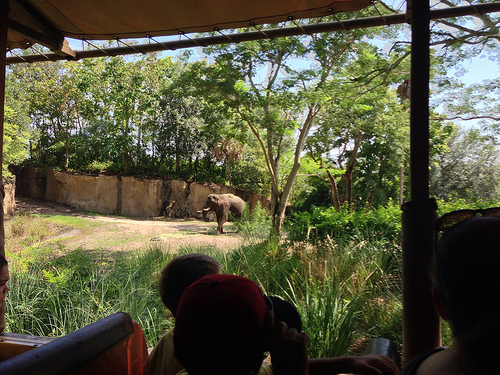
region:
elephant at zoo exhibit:
[179, 184, 265, 244]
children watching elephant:
[140, 227, 305, 369]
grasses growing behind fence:
[275, 235, 365, 335]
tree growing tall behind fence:
[229, 70, 304, 259]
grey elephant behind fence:
[195, 173, 262, 237]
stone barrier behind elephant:
[38, 140, 163, 226]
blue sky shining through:
[157, 44, 333, 137]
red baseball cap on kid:
[167, 264, 294, 359]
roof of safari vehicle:
[120, 9, 345, 132]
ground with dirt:
[92, 213, 164, 250]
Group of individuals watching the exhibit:
[149, 211, 496, 368]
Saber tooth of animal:
[198, 206, 211, 214]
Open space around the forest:
[4, 218, 215, 247]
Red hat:
[179, 281, 299, 349]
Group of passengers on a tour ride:
[149, 209, 495, 371]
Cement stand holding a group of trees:
[10, 166, 208, 217]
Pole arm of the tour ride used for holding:
[402, 23, 436, 358]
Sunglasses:
[434, 203, 495, 230]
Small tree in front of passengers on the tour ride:
[174, 35, 408, 238]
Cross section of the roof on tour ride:
[0, 3, 402, 75]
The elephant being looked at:
[193, 187, 253, 234]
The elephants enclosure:
[1, 24, 485, 363]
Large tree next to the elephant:
[189, 0, 372, 248]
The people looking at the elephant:
[129, 207, 496, 372]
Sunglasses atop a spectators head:
[432, 202, 498, 228]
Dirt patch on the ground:
[28, 212, 257, 256]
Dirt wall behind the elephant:
[23, 162, 254, 219]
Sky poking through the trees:
[13, 6, 495, 156]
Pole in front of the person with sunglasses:
[397, 2, 452, 364]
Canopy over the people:
[2, 0, 499, 67]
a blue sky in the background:
[0, 0, 499, 177]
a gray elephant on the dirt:
[195, 192, 249, 236]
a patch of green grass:
[39, 210, 105, 231]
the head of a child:
[153, 251, 224, 320]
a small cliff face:
[0, 162, 266, 214]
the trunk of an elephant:
[195, 202, 212, 225]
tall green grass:
[279, 252, 388, 356]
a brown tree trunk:
[243, 100, 328, 247]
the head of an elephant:
[193, 189, 221, 224]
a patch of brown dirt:
[98, 212, 176, 239]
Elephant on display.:
[188, 175, 258, 236]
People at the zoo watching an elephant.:
[158, 169, 329, 374]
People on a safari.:
[134, 168, 324, 370]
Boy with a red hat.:
[193, 253, 241, 341]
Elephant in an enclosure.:
[165, 103, 357, 302]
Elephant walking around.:
[66, 111, 256, 261]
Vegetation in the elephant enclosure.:
[286, 169, 386, 318]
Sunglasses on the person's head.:
[443, 186, 493, 233]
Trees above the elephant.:
[41, 79, 291, 166]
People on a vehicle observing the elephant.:
[39, 222, 359, 360]